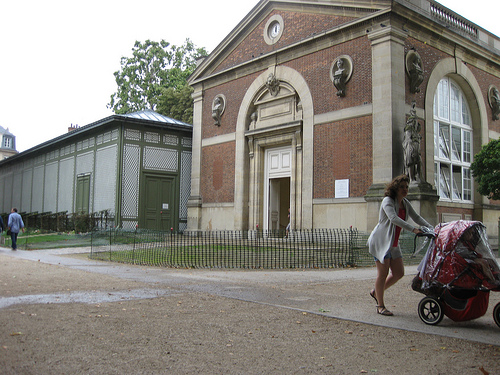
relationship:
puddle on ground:
[3, 281, 175, 321] [0, 246, 489, 373]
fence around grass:
[87, 219, 422, 277] [102, 237, 322, 274]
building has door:
[94, 109, 211, 246] [142, 175, 174, 230]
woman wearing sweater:
[370, 172, 439, 317] [367, 197, 433, 263]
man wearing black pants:
[4, 207, 26, 249] [9, 230, 19, 246]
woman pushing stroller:
[370, 172, 439, 317] [408, 216, 499, 333]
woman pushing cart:
[370, 172, 439, 317] [407, 210, 496, 335]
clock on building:
[261, 22, 284, 40] [181, 1, 498, 249]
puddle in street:
[3, 290, 153, 305] [0, 241, 497, 373]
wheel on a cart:
[415, 295, 444, 326] [407, 217, 499, 324]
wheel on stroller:
[418, 296, 444, 325] [411, 219, 498, 328]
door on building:
[68, 170, 98, 234] [0, 106, 191, 232]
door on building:
[132, 166, 180, 240] [0, 106, 191, 232]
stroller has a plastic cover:
[398, 217, 499, 330] [405, 208, 499, 322]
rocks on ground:
[5, 253, 495, 373] [4, 227, 498, 372]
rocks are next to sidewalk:
[5, 253, 495, 373] [0, 244, 498, 371]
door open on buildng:
[266, 176, 293, 238] [185, 1, 498, 257]